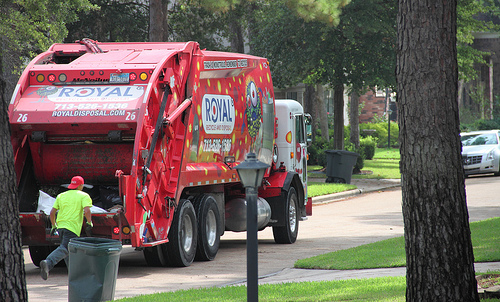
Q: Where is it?
A: This is at the street.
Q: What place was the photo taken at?
A: It was taken at the street.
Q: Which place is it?
A: It is a street.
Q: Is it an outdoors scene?
A: Yes, it is outdoors.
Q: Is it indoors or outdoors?
A: It is outdoors.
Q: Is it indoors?
A: No, it is outdoors.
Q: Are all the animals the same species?
A: Yes, all the animals are bears.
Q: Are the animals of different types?
A: No, all the animals are bears.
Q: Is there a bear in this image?
A: Yes, there are bears.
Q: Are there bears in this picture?
A: Yes, there are bears.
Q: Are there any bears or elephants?
A: Yes, there are bears.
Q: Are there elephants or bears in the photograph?
A: Yes, there are bears.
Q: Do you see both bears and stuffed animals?
A: No, there are bears but no stuffed animals.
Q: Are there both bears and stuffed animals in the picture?
A: No, there are bears but no stuffed animals.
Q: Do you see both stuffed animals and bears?
A: No, there are bears but no stuffed animals.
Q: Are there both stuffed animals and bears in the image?
A: No, there are bears but no stuffed animals.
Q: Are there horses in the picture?
A: No, there are no horses.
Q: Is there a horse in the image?
A: No, there are no horses.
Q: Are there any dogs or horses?
A: No, there are no horses or dogs.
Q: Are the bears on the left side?
A: Yes, the bears are on the left of the image.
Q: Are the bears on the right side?
A: No, the bears are on the left of the image.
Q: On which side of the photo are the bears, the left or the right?
A: The bears are on the left of the image.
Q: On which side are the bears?
A: The bears are on the left of the image.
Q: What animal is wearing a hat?
A: The bears are wearing a hat.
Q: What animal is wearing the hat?
A: The bears are wearing a hat.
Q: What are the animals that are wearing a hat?
A: The animals are bears.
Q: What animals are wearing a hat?
A: The animals are bears.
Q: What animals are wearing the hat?
A: The animals are bears.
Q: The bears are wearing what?
A: The bears are wearing a hat.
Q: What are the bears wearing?
A: The bears are wearing a hat.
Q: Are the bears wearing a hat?
A: Yes, the bears are wearing a hat.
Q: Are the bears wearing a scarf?
A: No, the bears are wearing a hat.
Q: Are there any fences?
A: No, there are no fences.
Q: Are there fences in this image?
A: No, there are no fences.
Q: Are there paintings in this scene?
A: No, there are no paintings.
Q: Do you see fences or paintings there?
A: No, there are no paintings or fences.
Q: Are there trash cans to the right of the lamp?
A: Yes, there is a trash can to the right of the lamp.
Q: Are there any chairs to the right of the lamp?
A: No, there is a trash can to the right of the lamp.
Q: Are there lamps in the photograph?
A: Yes, there is a lamp.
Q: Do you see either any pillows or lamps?
A: Yes, there is a lamp.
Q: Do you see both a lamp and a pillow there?
A: No, there is a lamp but no pillows.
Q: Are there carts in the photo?
A: No, there are no carts.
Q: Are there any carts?
A: No, there are no carts.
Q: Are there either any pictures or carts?
A: No, there are no carts or pictures.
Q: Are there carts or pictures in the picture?
A: No, there are no carts or pictures.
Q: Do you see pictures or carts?
A: No, there are no carts or pictures.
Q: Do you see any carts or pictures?
A: No, there are no carts or pictures.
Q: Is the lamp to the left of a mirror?
A: No, the lamp is to the left of the trash bin.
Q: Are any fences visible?
A: No, there are no fences.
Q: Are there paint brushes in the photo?
A: No, there are no paint brushes.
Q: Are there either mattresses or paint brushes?
A: No, there are no paint brushes or mattresses.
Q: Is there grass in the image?
A: Yes, there is grass.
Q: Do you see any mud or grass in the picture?
A: Yes, there is grass.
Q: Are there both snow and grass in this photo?
A: No, there is grass but no snow.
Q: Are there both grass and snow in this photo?
A: No, there is grass but no snow.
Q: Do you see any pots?
A: No, there are no pots.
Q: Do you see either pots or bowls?
A: No, there are no pots or bowls.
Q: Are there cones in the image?
A: No, there are no cones.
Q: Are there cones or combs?
A: No, there are no cones or combs.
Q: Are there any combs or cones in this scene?
A: No, there are no cones or combs.